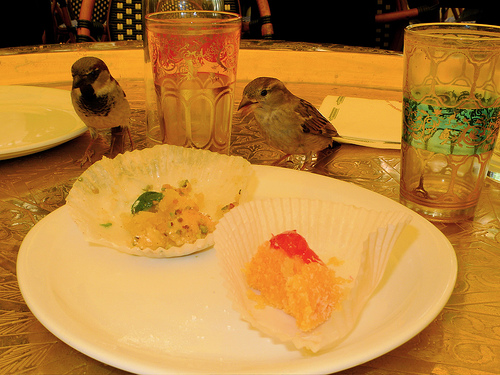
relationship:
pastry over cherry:
[111, 143, 243, 289] [196, 211, 328, 286]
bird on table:
[69, 55, 137, 167] [2, 40, 495, 373]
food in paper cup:
[247, 229, 345, 332] [65, 144, 257, 262]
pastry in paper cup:
[120, 178, 215, 250] [208, 194, 416, 352]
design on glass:
[150, 31, 236, 78] [138, 8, 238, 144]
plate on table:
[14, 161, 456, 374] [2, 40, 495, 373]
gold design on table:
[0, 178, 54, 273] [447, 302, 489, 358]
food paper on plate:
[63, 142, 258, 267] [14, 161, 456, 374]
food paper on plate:
[212, 196, 413, 354] [14, 161, 456, 374]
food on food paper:
[115, 115, 372, 322] [212, 196, 413, 354]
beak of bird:
[234, 98, 258, 121] [235, 75, 342, 170]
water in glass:
[153, 71, 235, 153] [148, 6, 238, 151]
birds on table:
[237, 76, 342, 171] [2, 40, 495, 373]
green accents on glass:
[402, 95, 498, 152] [399, 22, 500, 223]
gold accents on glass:
[399, 22, 496, 209] [399, 22, 500, 223]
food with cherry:
[247, 229, 345, 332] [274, 230, 319, 261]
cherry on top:
[274, 230, 319, 261] [266, 231, 317, 274]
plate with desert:
[14, 161, 456, 374] [221, 203, 383, 354]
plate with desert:
[14, 161, 456, 374] [73, 144, 248, 254]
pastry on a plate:
[120, 178, 215, 250] [14, 161, 456, 374]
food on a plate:
[247, 229, 345, 332] [14, 161, 456, 374]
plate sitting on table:
[18, 161, 465, 372] [2, 40, 495, 373]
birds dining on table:
[237, 76, 342, 171] [2, 40, 495, 373]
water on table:
[140, 9, 235, 149] [6, 123, 498, 370]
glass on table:
[399, 22, 500, 223] [4, 84, 496, 371]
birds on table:
[224, 55, 358, 182] [2, 40, 495, 373]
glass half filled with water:
[143, 8, 241, 154] [153, 71, 235, 153]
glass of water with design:
[143, 10, 241, 155] [146, 26, 240, 78]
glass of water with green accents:
[404, 22, 499, 227] [402, 87, 498, 154]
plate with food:
[14, 161, 456, 374] [115, 157, 377, 311]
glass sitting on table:
[399, 22, 500, 223] [410, 320, 490, 375]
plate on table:
[14, 161, 456, 374] [69, 52, 497, 233]